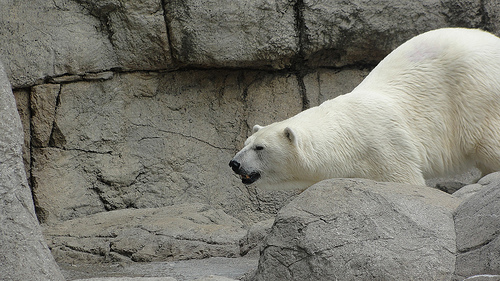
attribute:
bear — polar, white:
[229, 19, 477, 205]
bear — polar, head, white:
[222, 15, 464, 214]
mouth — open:
[240, 173, 263, 181]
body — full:
[226, 14, 471, 215]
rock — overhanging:
[106, 0, 366, 168]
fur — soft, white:
[416, 109, 459, 159]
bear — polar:
[225, 19, 469, 193]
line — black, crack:
[287, 13, 319, 107]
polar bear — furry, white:
[228, 29, 498, 189]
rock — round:
[250, 173, 446, 280]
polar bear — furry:
[219, 25, 499, 210]